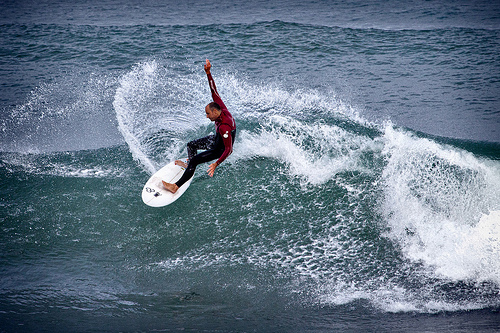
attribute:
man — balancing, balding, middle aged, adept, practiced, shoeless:
[161, 57, 237, 194]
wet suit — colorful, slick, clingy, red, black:
[176, 74, 235, 186]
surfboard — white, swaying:
[139, 157, 196, 208]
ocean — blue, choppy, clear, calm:
[0, 1, 499, 331]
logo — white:
[221, 129, 229, 140]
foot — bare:
[174, 155, 186, 171]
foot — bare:
[161, 179, 180, 193]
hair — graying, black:
[209, 102, 221, 111]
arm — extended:
[202, 57, 226, 108]